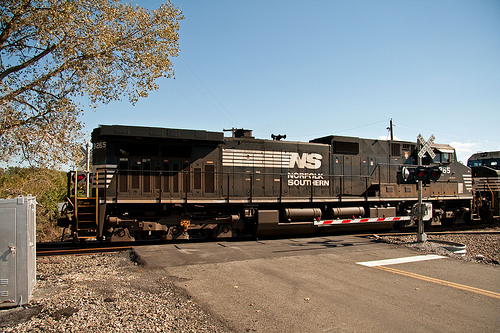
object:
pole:
[416, 138, 423, 234]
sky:
[0, 2, 499, 168]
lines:
[374, 264, 493, 299]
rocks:
[0, 246, 223, 332]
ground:
[34, 233, 500, 331]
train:
[58, 117, 499, 241]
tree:
[1, 1, 185, 174]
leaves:
[0, 0, 180, 162]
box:
[0, 196, 44, 304]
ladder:
[72, 166, 101, 248]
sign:
[411, 129, 438, 160]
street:
[131, 237, 498, 332]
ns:
[287, 150, 324, 169]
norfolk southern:
[284, 168, 329, 185]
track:
[37, 226, 499, 250]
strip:
[310, 214, 414, 226]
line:
[353, 253, 449, 268]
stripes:
[220, 147, 299, 167]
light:
[69, 164, 86, 184]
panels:
[107, 154, 220, 197]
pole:
[416, 136, 427, 242]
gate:
[310, 207, 409, 225]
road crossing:
[0, 205, 446, 253]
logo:
[217, 146, 336, 189]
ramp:
[127, 226, 377, 251]